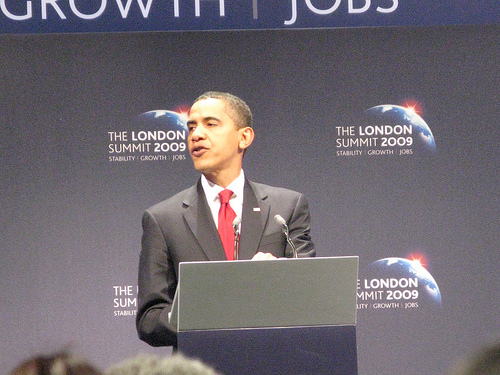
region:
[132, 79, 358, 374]
barack obama at a podium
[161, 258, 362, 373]
a podium is grey and blue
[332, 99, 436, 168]
logo for the london summit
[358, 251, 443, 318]
logo for the london summit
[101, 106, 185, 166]
logo for the london summit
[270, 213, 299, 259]
a microphone on a podium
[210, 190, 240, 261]
a red tie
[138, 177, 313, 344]
a man's black jacket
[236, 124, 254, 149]
ear of a man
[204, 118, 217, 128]
eye of a man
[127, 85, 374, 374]
man giving speech at podium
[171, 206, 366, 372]
podium where speech is being given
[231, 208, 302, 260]
set of mics for sound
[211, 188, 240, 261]
red tie on the man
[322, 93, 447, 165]
graphic on backdrop of podium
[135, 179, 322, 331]
jacket as part of attire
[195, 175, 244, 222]
white shirt underneath jacket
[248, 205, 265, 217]
bracket on flap of suit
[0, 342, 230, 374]
tops of heads of audience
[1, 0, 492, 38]
lettering on larger banner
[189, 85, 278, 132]
Man has short hair.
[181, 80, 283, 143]
Man has dark hair.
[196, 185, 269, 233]
Man wearing red tie.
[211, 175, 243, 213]
Man wearing white shirt.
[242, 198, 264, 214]
Pin on man's jacket.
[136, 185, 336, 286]
Man wearing dark jacket.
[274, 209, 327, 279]
Microphone on podium.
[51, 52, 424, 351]
Blue wall behind man.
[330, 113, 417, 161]
White writing on blue wall.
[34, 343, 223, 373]
Top of peoples heads.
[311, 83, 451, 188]
London Summit logo on background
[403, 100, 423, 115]
sun peaking over the earth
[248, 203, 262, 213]
lapel pin on the jacket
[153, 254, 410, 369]
podium in front of the room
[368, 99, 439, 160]
partial picture of the earth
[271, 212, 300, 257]
microphone on the podium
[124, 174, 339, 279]
suit and tie on the man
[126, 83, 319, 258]
president of the united states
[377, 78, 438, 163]
picture of the earth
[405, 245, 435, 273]
bright light on the picture of the earth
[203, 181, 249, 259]
Obama is wearig a red tie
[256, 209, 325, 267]
podium microphone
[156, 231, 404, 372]
podium in front of Obama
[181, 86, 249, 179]
Obama talking to the audience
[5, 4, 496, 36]
GROWING JOBS banner above Obama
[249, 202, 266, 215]
american flag pin on his jacket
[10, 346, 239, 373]
people in the audience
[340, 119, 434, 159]
THE LONDON SUMMIT 2009 on wall